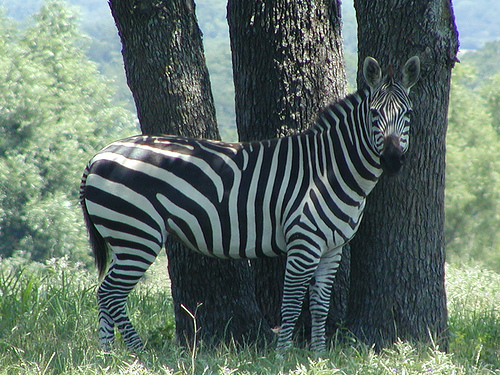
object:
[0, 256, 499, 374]
grass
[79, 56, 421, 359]
zebra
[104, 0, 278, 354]
trees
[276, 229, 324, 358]
legs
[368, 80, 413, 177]
face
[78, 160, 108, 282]
tail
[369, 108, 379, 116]
eyes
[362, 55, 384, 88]
ears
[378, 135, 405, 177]
nose